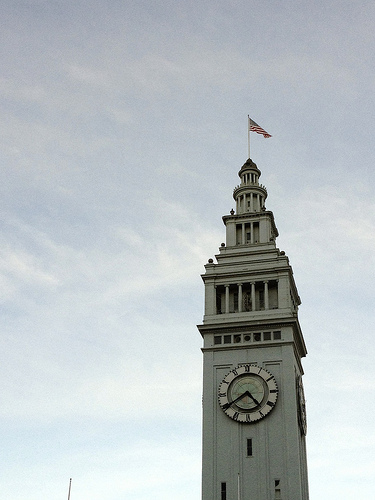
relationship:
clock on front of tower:
[217, 364, 279, 426] [194, 113, 310, 499]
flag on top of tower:
[247, 114, 273, 140] [194, 113, 310, 499]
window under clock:
[243, 435, 256, 458] [217, 364, 279, 426]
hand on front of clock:
[222, 389, 249, 410] [217, 364, 279, 426]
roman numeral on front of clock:
[243, 364, 251, 374] [217, 364, 279, 426]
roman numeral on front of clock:
[217, 390, 229, 399] [217, 364, 279, 426]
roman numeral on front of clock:
[220, 378, 231, 386] [217, 364, 279, 426]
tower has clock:
[194, 113, 310, 499] [217, 364, 279, 426]